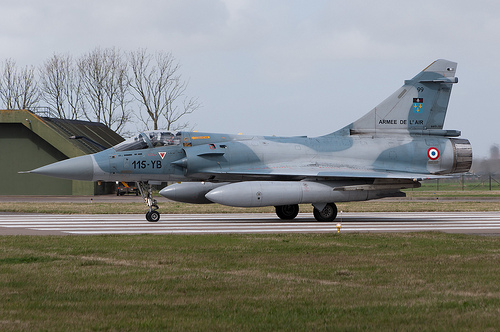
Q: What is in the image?
A: Jet.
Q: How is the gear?
A: Down.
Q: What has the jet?
A: Rockets.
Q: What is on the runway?
A: Jet.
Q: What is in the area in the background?
A: Trees.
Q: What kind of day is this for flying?
A: Cloudy.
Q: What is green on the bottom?
A: Grass on the ground.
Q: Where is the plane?
A: On the runway.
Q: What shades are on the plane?
A: Blues and gray.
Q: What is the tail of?
A: A plane.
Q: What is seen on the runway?
A: White marks.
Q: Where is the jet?
A: On the runway.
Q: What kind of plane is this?
A: A fighter jet.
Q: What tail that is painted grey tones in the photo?
A: Airplane on runway.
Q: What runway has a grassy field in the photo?
A: Runway where planes are flying.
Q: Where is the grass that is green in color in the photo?
A: Near runway.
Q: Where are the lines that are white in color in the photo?
A: On the runway.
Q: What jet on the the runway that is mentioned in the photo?
A: Grey and blue jet.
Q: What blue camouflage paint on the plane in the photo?
A: Plane with large wings.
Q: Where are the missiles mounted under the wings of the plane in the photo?
A: Side of plane.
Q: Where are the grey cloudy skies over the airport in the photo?
A: Behind the airplane.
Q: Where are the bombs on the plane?
A: Under the wings.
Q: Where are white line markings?
A: On the tarmac.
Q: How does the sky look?
A: Cloudy and misty.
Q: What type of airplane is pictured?
A: A French army jet.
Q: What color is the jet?
A: Grey and blue.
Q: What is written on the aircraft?
A: "ARMEE DE L'AIR".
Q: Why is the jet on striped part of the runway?
A: The jet is about to take off.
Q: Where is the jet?
A: On the runway landing.